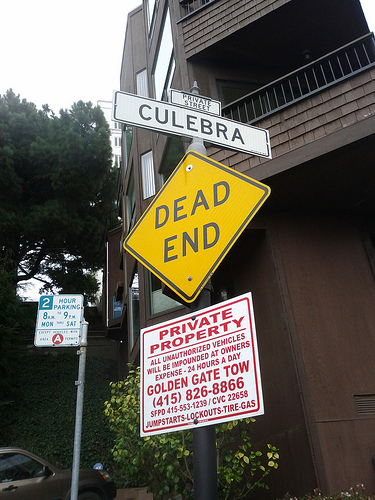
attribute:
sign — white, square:
[128, 321, 282, 411]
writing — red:
[140, 351, 262, 415]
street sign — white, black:
[117, 82, 291, 167]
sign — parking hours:
[18, 282, 75, 351]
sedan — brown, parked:
[37, 462, 54, 485]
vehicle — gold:
[2, 446, 114, 498]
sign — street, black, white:
[110, 85, 277, 161]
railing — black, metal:
[217, 30, 360, 130]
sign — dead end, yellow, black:
[117, 148, 274, 303]